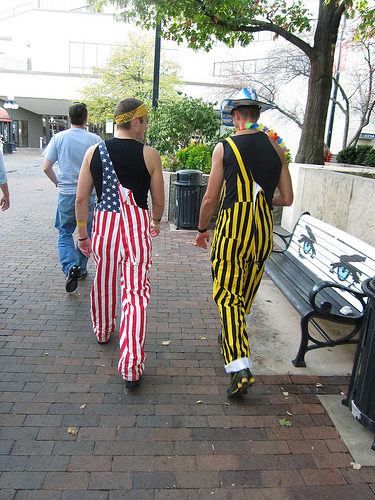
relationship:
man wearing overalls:
[72, 97, 164, 390] [87, 136, 153, 383]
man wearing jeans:
[39, 99, 103, 294] [54, 192, 97, 294]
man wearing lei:
[191, 82, 292, 401] [233, 121, 292, 163]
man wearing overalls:
[191, 82, 292, 401] [208, 139, 278, 373]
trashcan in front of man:
[171, 167, 208, 232] [191, 82, 292, 401]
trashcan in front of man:
[171, 167, 208, 232] [72, 97, 164, 390]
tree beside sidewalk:
[202, 10, 367, 153] [25, 248, 331, 462]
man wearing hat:
[191, 82, 292, 401] [222, 79, 278, 114]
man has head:
[191, 82, 292, 401] [210, 79, 271, 130]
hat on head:
[215, 88, 272, 106] [210, 79, 271, 130]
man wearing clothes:
[191, 82, 292, 401] [208, 134, 281, 367]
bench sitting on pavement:
[281, 197, 366, 308] [242, 279, 366, 375]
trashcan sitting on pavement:
[171, 167, 208, 232] [169, 240, 216, 335]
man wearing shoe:
[39, 99, 103, 294] [57, 264, 93, 308]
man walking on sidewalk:
[191, 82, 292, 401] [159, 236, 204, 403]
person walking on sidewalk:
[40, 102, 103, 292] [159, 236, 204, 403]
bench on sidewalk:
[281, 197, 366, 308] [7, 158, 373, 498]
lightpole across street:
[125, 25, 181, 106] [4, 150, 44, 163]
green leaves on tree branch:
[156, 99, 216, 137] [240, 13, 312, 55]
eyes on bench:
[292, 215, 365, 287] [265, 204, 374, 382]